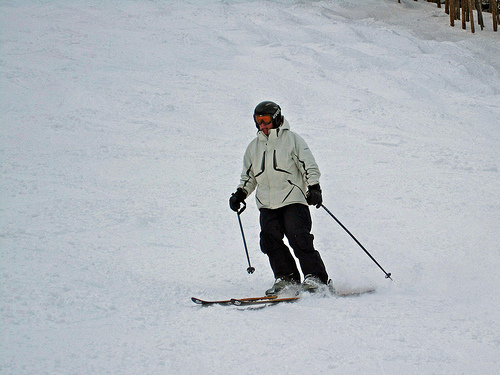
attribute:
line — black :
[272, 177, 309, 199]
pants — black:
[264, 160, 314, 182]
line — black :
[280, 184, 295, 206]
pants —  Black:
[239, 197, 344, 304]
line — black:
[243, 163, 252, 185]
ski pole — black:
[316, 203, 393, 280]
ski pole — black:
[231, 192, 256, 274]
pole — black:
[301, 192, 395, 279]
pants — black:
[202, 205, 379, 290]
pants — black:
[242, 200, 372, 277]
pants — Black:
[259, 205, 324, 279]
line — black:
[288, 148, 314, 186]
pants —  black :
[256, 205, 331, 287]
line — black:
[253, 150, 265, 179]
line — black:
[270, 147, 293, 175]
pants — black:
[251, 201, 331, 286]